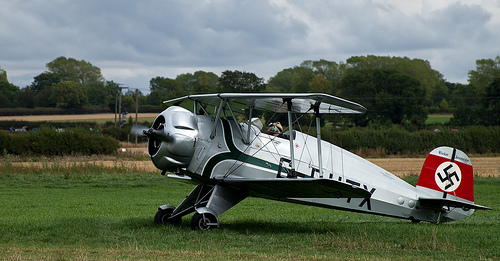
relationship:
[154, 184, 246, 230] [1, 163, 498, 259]
landing gear on grass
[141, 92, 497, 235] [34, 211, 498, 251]
airplane on ground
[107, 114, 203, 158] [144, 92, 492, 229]
propeller on airplane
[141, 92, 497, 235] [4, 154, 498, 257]
airplane on ground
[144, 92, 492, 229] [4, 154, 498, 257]
airplane on ground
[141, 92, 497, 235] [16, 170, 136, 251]
airplane on ground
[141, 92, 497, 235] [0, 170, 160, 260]
airplane on ground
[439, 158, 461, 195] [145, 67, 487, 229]
swastika on plane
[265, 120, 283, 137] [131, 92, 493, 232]
pilot in plane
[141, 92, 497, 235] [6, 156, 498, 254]
airplane landed in field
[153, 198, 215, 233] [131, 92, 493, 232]
wheels on plane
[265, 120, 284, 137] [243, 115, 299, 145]
pilot sitting in cockpit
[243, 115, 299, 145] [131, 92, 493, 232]
cockpit of plane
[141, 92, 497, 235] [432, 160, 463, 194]
airplane with swastika symbol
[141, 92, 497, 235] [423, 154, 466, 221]
airplane with swastika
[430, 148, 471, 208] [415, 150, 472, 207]
swastika on a tailfin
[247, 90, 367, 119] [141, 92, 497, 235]
leftwing of a airplane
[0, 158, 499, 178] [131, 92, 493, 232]
sand beyond plane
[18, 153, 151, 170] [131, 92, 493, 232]
sand beyond plane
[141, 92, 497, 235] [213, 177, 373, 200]
airplane has leftwing